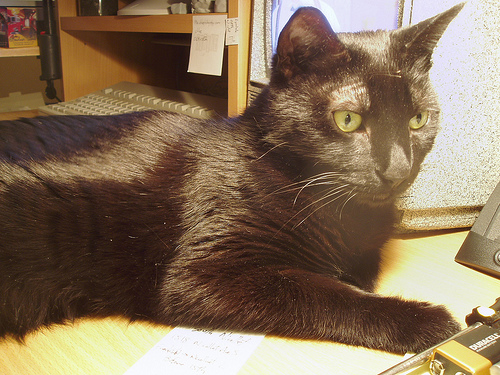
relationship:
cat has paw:
[70, 12, 451, 336] [331, 291, 474, 372]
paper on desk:
[188, 13, 227, 82] [62, 320, 159, 358]